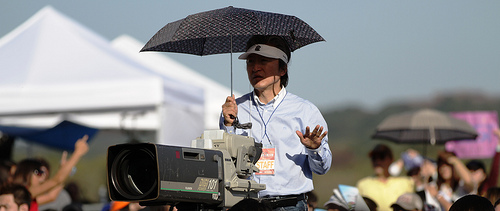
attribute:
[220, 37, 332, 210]
person — standing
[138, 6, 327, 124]
umbrella — black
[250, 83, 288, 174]
tag — red, yellow, white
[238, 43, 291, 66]
visor — white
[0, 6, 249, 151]
tent — white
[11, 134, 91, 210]
woman — pointing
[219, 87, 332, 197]
shirt — blue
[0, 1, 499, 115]
sky — blue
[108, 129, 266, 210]
camera — big, black, grey, large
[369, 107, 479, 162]
umbrella — grey, brown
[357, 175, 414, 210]
shirt — yellow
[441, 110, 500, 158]
square — pink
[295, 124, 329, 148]
hand — outstretched, raised